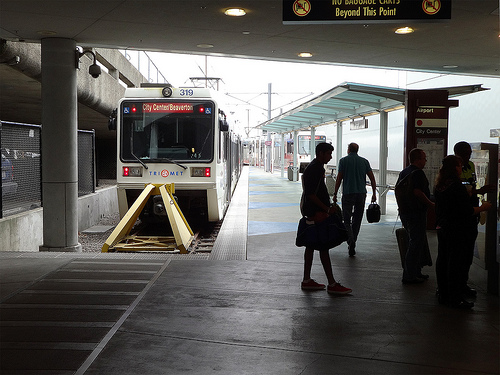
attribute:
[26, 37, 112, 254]
support post — concrete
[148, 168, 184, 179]
number written — blue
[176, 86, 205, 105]
numbered 319 — black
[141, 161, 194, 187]
tri met sign — blue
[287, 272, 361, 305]
shoes — red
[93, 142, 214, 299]
train — yellow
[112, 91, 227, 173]
lights — red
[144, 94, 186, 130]
letters — white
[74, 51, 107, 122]
column — white